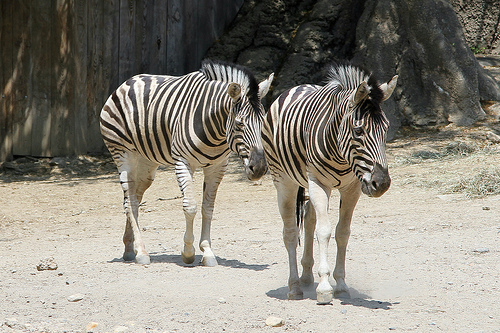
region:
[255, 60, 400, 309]
zebra walking n the dirt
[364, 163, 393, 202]
black nose on face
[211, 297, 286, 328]
beige rocks in dirt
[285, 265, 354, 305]
four white hooves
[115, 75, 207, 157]
black and white stripes on back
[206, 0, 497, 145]
massive brown tree trunk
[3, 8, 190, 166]
shadow cast by tree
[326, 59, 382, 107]
black and white striped mane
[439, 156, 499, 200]
dead brown grass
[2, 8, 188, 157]
wooden fence slats of enclosure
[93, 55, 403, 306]
Two zebras side by side.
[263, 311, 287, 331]
A small rock on the ground.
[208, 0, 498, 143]
A huge tree trunk.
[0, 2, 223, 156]
A wooden wall.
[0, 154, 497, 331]
A rocky ground.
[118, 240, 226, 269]
A zebra's hooves.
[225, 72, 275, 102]
A zebra's ears.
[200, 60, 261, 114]
Hair on the back of a zebra.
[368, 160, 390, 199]
A zebra's nose.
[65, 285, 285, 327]
A few rocks on the ground.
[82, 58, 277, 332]
black and white zebra walking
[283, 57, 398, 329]
black and white zebra walking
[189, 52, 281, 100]
stiff mane on zebra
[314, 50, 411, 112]
stiff mane on zebra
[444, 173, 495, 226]
patches of grass on right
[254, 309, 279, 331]
small rocks on the dirt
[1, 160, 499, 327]
dirt ground under zebras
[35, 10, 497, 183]
large tree trunk behind zebras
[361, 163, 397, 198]
black nose of zebra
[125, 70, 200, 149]
white and black stripes o zebra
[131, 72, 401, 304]
two zebras are walking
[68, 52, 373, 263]
the zebras are stripped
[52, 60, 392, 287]
they are black and white in colour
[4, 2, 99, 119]
the wall is wooden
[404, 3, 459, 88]
the stone is black in colour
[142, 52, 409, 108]
they have raised black hair on their back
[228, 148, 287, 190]
theirv mouth are black in colour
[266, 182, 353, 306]
their legs are white in colour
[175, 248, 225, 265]
the hooves are black in colour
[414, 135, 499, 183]
the grass is dry on the ground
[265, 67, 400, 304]
a zebra standing on dirt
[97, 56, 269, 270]
a zebra standing on dirt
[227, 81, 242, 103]
ear of a zebra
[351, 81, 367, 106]
ear of a zebra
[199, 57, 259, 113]
mane of a zebra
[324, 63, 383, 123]
mane of a zebra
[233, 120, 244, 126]
eye of a zebra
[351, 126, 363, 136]
eye of a zebra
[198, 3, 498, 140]
trunk of a large tree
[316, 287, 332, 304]
a zebra's hoof